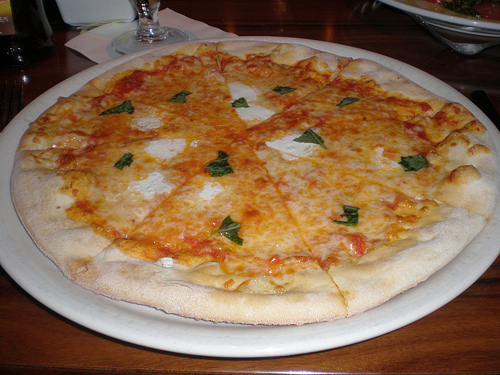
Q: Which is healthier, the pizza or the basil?
A: The basil is healthier than the pizza.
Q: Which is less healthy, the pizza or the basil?
A: The pizza is less healthy than the basil.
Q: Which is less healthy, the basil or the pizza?
A: The pizza is less healthy than the basil.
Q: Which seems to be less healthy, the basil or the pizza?
A: The pizza is less healthy than the basil.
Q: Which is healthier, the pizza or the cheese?
A: The cheese is healthier than the pizza.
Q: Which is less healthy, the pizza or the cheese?
A: The pizza is less healthy than the cheese.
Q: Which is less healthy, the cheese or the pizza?
A: The pizza is less healthy than the cheese.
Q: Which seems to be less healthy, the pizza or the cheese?
A: The pizza is less healthy than the cheese.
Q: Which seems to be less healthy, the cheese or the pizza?
A: The pizza is less healthy than the cheese.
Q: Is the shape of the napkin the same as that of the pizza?
A: No, the pizza is round and the napkin is square.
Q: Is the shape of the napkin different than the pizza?
A: Yes, the pizza is round and the napkin is square.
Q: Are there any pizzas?
A: Yes, there is a pizza.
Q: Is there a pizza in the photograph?
A: Yes, there is a pizza.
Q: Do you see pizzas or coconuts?
A: Yes, there is a pizza.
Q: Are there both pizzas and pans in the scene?
A: No, there is a pizza but no pans.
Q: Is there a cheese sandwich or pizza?
A: Yes, there is a cheese pizza.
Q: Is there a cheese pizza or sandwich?
A: Yes, there is a cheese pizza.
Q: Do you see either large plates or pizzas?
A: Yes, there is a large pizza.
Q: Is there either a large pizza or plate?
A: Yes, there is a large pizza.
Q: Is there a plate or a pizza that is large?
A: Yes, the pizza is large.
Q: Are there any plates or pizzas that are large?
A: Yes, the pizza is large.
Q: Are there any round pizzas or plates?
A: Yes, there is a round pizza.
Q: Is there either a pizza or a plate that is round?
A: Yes, the pizza is round.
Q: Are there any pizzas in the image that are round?
A: Yes, there is a round pizza.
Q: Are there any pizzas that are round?
A: Yes, there is a pizza that is round.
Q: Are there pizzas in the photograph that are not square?
A: Yes, there is a round pizza.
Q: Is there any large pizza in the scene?
A: Yes, there is a large pizza.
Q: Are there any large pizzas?
A: Yes, there is a large pizza.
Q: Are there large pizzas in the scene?
A: Yes, there is a large pizza.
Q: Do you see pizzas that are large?
A: Yes, there is a pizza that is large.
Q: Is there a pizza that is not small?
A: Yes, there is a large pizza.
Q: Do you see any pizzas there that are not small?
A: Yes, there is a large pizza.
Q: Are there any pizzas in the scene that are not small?
A: Yes, there is a large pizza.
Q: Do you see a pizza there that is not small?
A: Yes, there is a large pizza.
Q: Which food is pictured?
A: The food is a pizza.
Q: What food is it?
A: The food is a pizza.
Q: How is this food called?
A: This is a pizza.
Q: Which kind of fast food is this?
A: This is a pizza.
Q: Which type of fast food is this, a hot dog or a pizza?
A: This is a pizza.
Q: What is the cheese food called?
A: The food is a pizza.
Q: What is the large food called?
A: The food is a pizza.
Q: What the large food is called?
A: The food is a pizza.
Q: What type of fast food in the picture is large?
A: The fast food is a pizza.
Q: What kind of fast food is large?
A: The fast food is a pizza.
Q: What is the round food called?
A: The food is a pizza.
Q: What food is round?
A: The food is a pizza.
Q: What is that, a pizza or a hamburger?
A: That is a pizza.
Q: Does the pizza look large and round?
A: Yes, the pizza is large and round.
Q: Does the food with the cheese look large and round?
A: Yes, the pizza is large and round.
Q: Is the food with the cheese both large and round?
A: Yes, the pizza is large and round.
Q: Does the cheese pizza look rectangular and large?
A: No, the pizza is large but round.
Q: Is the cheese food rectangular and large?
A: No, the pizza is large but round.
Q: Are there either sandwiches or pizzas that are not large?
A: No, there is a pizza but it is large.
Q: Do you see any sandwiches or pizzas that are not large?
A: No, there is a pizza but it is large.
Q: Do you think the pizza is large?
A: Yes, the pizza is large.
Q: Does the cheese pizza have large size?
A: Yes, the pizza is large.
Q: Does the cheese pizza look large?
A: Yes, the pizza is large.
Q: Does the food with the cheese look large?
A: Yes, the pizza is large.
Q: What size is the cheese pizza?
A: The pizza is large.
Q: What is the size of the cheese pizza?
A: The pizza is large.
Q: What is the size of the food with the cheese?
A: The pizza is large.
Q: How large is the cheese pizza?
A: The pizza is large.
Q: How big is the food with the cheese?
A: The pizza is large.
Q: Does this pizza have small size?
A: No, the pizza is large.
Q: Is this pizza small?
A: No, the pizza is large.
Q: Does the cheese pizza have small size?
A: No, the pizza is large.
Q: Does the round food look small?
A: No, the pizza is large.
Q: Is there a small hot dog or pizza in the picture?
A: No, there is a pizza but it is large.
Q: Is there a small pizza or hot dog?
A: No, there is a pizza but it is large.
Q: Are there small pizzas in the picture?
A: No, there is a pizza but it is large.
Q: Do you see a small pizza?
A: No, there is a pizza but it is large.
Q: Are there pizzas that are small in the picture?
A: No, there is a pizza but it is large.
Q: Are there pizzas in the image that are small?
A: No, there is a pizza but it is large.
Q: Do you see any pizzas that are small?
A: No, there is a pizza but it is large.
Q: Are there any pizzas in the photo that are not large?
A: No, there is a pizza but it is large.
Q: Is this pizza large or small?
A: The pizza is large.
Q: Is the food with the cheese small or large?
A: The pizza is large.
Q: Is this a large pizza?
A: Yes, this is a large pizza.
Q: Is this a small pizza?
A: No, this is a large pizza.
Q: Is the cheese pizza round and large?
A: Yes, the pizza is round and large.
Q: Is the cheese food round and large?
A: Yes, the pizza is round and large.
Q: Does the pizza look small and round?
A: No, the pizza is round but large.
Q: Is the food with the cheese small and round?
A: No, the pizza is round but large.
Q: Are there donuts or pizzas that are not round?
A: No, there is a pizza but it is round.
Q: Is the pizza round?
A: Yes, the pizza is round.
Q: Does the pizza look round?
A: Yes, the pizza is round.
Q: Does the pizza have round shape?
A: Yes, the pizza is round.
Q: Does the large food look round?
A: Yes, the pizza is round.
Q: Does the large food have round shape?
A: Yes, the pizza is round.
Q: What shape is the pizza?
A: The pizza is round.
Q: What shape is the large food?
A: The pizza is round.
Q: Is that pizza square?
A: No, the pizza is round.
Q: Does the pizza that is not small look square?
A: No, the pizza is round.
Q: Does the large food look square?
A: No, the pizza is round.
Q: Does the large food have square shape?
A: No, the pizza is round.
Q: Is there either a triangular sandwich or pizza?
A: No, there is a pizza but it is round.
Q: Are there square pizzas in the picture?
A: No, there is a pizza but it is round.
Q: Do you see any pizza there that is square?
A: No, there is a pizza but it is round.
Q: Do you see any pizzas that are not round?
A: No, there is a pizza but it is round.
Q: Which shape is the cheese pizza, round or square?
A: The pizza is round.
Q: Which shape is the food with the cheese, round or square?
A: The pizza is round.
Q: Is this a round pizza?
A: Yes, this is a round pizza.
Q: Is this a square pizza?
A: No, this is a round pizza.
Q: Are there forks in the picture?
A: Yes, there is a fork.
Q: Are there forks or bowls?
A: Yes, there is a fork.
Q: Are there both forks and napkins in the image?
A: Yes, there are both a fork and a napkin.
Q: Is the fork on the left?
A: Yes, the fork is on the left of the image.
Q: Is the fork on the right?
A: No, the fork is on the left of the image.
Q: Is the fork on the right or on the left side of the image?
A: The fork is on the left of the image.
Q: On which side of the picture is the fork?
A: The fork is on the left of the image.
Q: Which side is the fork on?
A: The fork is on the left of the image.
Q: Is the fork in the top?
A: Yes, the fork is in the top of the image.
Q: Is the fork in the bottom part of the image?
A: No, the fork is in the top of the image.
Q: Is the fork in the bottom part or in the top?
A: The fork is in the top of the image.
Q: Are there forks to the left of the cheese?
A: Yes, there is a fork to the left of the cheese.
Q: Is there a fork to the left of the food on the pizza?
A: Yes, there is a fork to the left of the cheese.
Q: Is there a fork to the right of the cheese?
A: No, the fork is to the left of the cheese.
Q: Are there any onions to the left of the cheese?
A: No, there is a fork to the left of the cheese.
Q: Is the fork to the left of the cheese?
A: Yes, the fork is to the left of the cheese.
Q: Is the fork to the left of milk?
A: No, the fork is to the left of the cheese.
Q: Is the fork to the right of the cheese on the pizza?
A: No, the fork is to the left of the cheese.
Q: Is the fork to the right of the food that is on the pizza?
A: No, the fork is to the left of the cheese.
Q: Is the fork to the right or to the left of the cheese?
A: The fork is to the left of the cheese.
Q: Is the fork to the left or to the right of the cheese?
A: The fork is to the left of the cheese.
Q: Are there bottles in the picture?
A: Yes, there is a bottle.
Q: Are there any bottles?
A: Yes, there is a bottle.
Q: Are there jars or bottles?
A: Yes, there is a bottle.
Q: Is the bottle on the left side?
A: Yes, the bottle is on the left of the image.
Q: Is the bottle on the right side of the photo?
A: No, the bottle is on the left of the image.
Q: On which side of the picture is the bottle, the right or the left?
A: The bottle is on the left of the image.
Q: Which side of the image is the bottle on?
A: The bottle is on the left of the image.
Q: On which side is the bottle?
A: The bottle is on the left of the image.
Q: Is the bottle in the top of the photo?
A: Yes, the bottle is in the top of the image.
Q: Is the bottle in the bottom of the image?
A: No, the bottle is in the top of the image.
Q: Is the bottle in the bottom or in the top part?
A: The bottle is in the top of the image.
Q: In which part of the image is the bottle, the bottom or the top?
A: The bottle is in the top of the image.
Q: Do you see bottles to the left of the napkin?
A: Yes, there is a bottle to the left of the napkin.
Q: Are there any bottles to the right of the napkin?
A: No, the bottle is to the left of the napkin.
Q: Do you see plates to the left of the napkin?
A: No, there is a bottle to the left of the napkin.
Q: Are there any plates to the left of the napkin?
A: No, there is a bottle to the left of the napkin.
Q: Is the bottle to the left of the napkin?
A: Yes, the bottle is to the left of the napkin.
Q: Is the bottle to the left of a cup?
A: No, the bottle is to the left of the napkin.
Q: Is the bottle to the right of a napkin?
A: No, the bottle is to the left of a napkin.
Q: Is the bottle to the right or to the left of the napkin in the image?
A: The bottle is to the left of the napkin.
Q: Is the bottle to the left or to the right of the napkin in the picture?
A: The bottle is to the left of the napkin.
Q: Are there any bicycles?
A: No, there are no bicycles.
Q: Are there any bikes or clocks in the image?
A: No, there are no bikes or clocks.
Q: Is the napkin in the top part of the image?
A: Yes, the napkin is in the top of the image.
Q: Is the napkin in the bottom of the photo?
A: No, the napkin is in the top of the image.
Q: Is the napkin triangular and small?
A: No, the napkin is small but square.